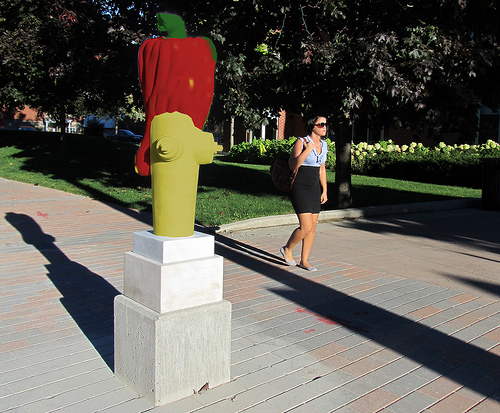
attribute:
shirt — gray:
[295, 134, 330, 169]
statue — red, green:
[119, 11, 264, 261]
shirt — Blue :
[293, 129, 330, 169]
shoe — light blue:
[271, 243, 302, 272]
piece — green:
[157, 12, 217, 60]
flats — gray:
[276, 246, 318, 274]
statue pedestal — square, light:
[112, 229, 232, 406]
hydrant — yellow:
[119, 104, 237, 241]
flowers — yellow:
[352, 137, 498, 157]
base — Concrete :
[102, 296, 232, 406]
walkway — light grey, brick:
[4, 176, 498, 412]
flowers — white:
[382, 135, 427, 166]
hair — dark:
[302, 111, 316, 126]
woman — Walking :
[237, 93, 375, 287]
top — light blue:
[296, 135, 327, 167]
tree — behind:
[221, 6, 493, 208]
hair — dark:
[292, 111, 330, 137]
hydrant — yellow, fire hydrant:
[143, 113, 221, 230]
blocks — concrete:
[157, 242, 217, 382]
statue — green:
[137, 16, 219, 236]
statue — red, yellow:
[132, 93, 263, 211]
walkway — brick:
[32, 161, 432, 406]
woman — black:
[272, 108, 342, 279]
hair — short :
[299, 103, 340, 147]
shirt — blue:
[288, 132, 328, 154]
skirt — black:
[277, 162, 347, 217]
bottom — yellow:
[149, 111, 240, 222]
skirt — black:
[285, 165, 322, 215]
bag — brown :
[265, 141, 298, 190]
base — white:
[111, 230, 233, 405]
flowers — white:
[371, 141, 401, 153]